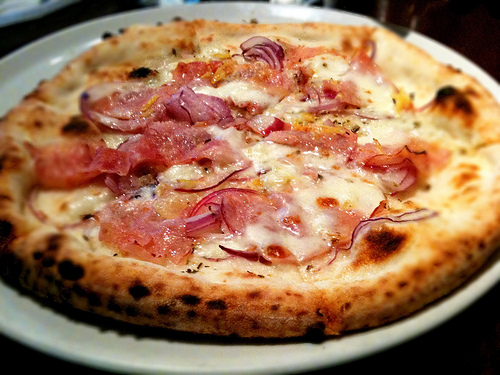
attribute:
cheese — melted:
[11, 35, 488, 287]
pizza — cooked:
[40, 36, 433, 300]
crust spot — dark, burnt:
[434, 82, 475, 123]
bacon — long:
[17, 114, 243, 190]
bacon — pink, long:
[78, 116, 249, 191]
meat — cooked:
[52, 115, 237, 185]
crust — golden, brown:
[132, 260, 217, 332]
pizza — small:
[5, 12, 494, 345]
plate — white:
[5, 4, 497, 370]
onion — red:
[356, 194, 403, 243]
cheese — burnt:
[166, 190, 321, 245]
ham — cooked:
[146, 88, 219, 125]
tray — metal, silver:
[3, 3, 499, 373]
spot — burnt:
[0, 213, 20, 251]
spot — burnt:
[29, 231, 65, 276]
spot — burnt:
[52, 255, 89, 285]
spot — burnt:
[125, 276, 154, 305]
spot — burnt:
[112, 298, 154, 321]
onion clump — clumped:
[240, 31, 288, 72]